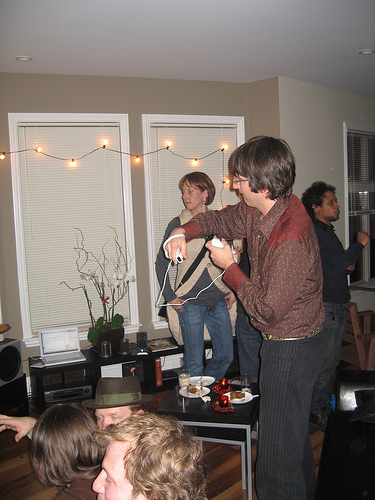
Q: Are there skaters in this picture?
A: No, there are no skaters.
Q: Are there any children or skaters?
A: No, there are no skaters or children.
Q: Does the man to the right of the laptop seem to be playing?
A: Yes, the man is playing.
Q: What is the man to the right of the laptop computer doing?
A: The man is playing.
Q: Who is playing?
A: The man is playing.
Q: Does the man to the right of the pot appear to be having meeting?
A: No, the man is playing.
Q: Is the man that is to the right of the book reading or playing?
A: The man is playing.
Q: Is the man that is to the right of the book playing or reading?
A: The man is playing.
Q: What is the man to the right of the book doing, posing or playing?
A: The man is playing.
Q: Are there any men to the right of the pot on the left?
A: Yes, there is a man to the right of the pot.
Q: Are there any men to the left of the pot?
A: No, the man is to the right of the pot.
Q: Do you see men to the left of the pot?
A: No, the man is to the right of the pot.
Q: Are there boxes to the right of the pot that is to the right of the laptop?
A: No, there is a man to the right of the pot.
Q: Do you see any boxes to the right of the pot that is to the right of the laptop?
A: No, there is a man to the right of the pot.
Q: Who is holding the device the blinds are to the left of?
A: The man is holding the Wii controller.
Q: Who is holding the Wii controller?
A: The man is holding the Wii controller.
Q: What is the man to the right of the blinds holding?
A: The man is holding the Wii remotes.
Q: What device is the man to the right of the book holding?
A: The man is holding the Wii remotes.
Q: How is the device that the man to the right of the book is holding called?
A: The device is a Wii controller.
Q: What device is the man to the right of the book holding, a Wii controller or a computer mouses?
A: The man is holding a Wii controller.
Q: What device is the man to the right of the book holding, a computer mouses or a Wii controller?
A: The man is holding a Wii controller.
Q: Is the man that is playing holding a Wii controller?
A: Yes, the man is holding a Wii controller.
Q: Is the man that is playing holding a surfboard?
A: No, the man is holding a Wii controller.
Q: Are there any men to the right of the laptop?
A: Yes, there is a man to the right of the laptop.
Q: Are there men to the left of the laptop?
A: No, the man is to the right of the laptop.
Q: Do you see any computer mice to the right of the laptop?
A: No, there is a man to the right of the laptop.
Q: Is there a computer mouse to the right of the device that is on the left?
A: No, there is a man to the right of the laptop.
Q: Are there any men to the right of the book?
A: Yes, there is a man to the right of the book.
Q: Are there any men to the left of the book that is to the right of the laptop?
A: No, the man is to the right of the book.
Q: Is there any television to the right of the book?
A: No, there is a man to the right of the book.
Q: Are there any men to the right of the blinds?
A: Yes, there is a man to the right of the blinds.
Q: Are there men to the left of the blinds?
A: No, the man is to the right of the blinds.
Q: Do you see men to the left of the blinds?
A: No, the man is to the right of the blinds.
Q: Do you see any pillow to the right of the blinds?
A: No, there is a man to the right of the blinds.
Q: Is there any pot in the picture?
A: Yes, there is a pot.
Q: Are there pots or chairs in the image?
A: Yes, there is a pot.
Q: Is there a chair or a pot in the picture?
A: Yes, there is a pot.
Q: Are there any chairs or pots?
A: Yes, there is a pot.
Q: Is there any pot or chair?
A: Yes, there is a pot.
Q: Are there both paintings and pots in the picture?
A: No, there is a pot but no paintings.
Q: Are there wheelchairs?
A: No, there are no wheelchairs.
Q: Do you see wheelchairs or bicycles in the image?
A: No, there are no wheelchairs or bicycles.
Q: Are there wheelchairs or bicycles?
A: No, there are no wheelchairs or bicycles.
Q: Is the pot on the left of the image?
A: Yes, the pot is on the left of the image.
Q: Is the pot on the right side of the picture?
A: No, the pot is on the left of the image.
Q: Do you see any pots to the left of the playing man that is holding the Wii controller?
A: Yes, there is a pot to the left of the man.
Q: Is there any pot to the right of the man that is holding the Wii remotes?
A: No, the pot is to the left of the man.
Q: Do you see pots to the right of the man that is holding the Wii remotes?
A: No, the pot is to the left of the man.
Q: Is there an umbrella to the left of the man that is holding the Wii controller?
A: No, there is a pot to the left of the man.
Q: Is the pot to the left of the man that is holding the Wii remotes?
A: Yes, the pot is to the left of the man.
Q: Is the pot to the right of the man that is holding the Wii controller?
A: No, the pot is to the left of the man.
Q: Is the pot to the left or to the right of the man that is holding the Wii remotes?
A: The pot is to the left of the man.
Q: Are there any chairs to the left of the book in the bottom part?
A: No, there is a pot to the left of the book.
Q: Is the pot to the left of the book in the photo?
A: Yes, the pot is to the left of the book.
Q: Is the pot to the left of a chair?
A: No, the pot is to the left of the book.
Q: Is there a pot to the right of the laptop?
A: Yes, there is a pot to the right of the laptop.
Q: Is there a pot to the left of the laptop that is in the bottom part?
A: No, the pot is to the right of the laptop.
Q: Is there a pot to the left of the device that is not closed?
A: No, the pot is to the right of the laptop.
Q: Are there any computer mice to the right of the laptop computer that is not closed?
A: No, there is a pot to the right of the laptop.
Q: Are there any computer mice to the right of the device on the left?
A: No, there is a pot to the right of the laptop.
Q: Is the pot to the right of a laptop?
A: Yes, the pot is to the right of a laptop.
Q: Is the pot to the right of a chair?
A: No, the pot is to the right of a laptop.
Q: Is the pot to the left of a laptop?
A: No, the pot is to the right of a laptop.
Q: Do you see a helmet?
A: No, there are no helmets.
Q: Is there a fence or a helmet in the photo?
A: No, there are no helmets or fences.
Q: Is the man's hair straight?
A: No, the hair is curly.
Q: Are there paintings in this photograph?
A: No, there are no paintings.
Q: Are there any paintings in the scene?
A: No, there are no paintings.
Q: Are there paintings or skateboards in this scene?
A: No, there are no paintings or skateboards.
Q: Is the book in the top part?
A: No, the book is in the bottom of the image.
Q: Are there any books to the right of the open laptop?
A: Yes, there is a book to the right of the laptop computer.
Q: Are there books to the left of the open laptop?
A: No, the book is to the right of the laptop computer.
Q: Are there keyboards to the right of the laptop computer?
A: No, there is a book to the right of the laptop computer.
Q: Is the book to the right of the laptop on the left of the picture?
A: Yes, the book is to the right of the laptop.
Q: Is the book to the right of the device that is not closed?
A: Yes, the book is to the right of the laptop.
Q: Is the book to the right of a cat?
A: No, the book is to the right of the laptop.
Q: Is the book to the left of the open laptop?
A: No, the book is to the right of the laptop computer.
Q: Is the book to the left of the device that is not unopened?
A: No, the book is to the right of the laptop computer.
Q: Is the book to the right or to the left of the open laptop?
A: The book is to the right of the laptop.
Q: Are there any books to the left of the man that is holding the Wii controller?
A: Yes, there is a book to the left of the man.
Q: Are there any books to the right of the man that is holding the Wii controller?
A: No, the book is to the left of the man.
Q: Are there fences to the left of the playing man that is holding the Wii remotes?
A: No, there is a book to the left of the man.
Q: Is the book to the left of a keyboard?
A: No, the book is to the left of the man.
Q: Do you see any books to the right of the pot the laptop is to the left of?
A: Yes, there is a book to the right of the pot.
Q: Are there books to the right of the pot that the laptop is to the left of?
A: Yes, there is a book to the right of the pot.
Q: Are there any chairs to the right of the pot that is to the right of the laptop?
A: No, there is a book to the right of the pot.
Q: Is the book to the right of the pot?
A: Yes, the book is to the right of the pot.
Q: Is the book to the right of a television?
A: No, the book is to the right of the pot.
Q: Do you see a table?
A: Yes, there is a table.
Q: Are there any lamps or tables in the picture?
A: Yes, there is a table.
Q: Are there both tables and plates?
A: Yes, there are both a table and a plate.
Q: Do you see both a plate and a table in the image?
A: Yes, there are both a table and a plate.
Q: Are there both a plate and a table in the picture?
A: Yes, there are both a table and a plate.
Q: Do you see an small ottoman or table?
A: Yes, there is a small table.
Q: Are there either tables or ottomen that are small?
A: Yes, the table is small.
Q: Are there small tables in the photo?
A: Yes, there is a small table.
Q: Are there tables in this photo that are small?
A: Yes, there is a table that is small.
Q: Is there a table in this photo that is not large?
A: Yes, there is a small table.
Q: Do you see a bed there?
A: No, there are no beds.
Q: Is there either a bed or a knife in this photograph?
A: No, there are no beds or knives.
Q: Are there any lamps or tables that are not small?
A: No, there is a table but it is small.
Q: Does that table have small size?
A: Yes, the table is small.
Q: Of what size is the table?
A: The table is small.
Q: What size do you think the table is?
A: The table is small.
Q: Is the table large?
A: No, the table is small.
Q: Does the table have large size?
A: No, the table is small.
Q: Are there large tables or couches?
A: No, there is a table but it is small.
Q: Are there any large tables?
A: No, there is a table but it is small.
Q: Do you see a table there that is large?
A: No, there is a table but it is small.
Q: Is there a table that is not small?
A: No, there is a table but it is small.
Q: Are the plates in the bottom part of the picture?
A: Yes, the plates are in the bottom of the image.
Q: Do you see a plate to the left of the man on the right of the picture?
A: Yes, there are plates to the left of the man.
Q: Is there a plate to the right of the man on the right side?
A: No, the plates are to the left of the man.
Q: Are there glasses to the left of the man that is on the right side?
A: No, there are plates to the left of the man.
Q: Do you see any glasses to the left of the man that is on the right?
A: No, there are plates to the left of the man.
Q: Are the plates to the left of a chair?
A: No, the plates are to the left of the man.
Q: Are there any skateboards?
A: No, there are no skateboards.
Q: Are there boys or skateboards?
A: No, there are no skateboards or boys.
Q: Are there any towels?
A: No, there are no towels.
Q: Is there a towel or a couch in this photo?
A: No, there are no towels or couches.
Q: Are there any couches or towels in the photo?
A: No, there are no towels or couches.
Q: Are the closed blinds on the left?
A: Yes, the blinds are on the left of the image.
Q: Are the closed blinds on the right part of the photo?
A: No, the blinds are on the left of the image.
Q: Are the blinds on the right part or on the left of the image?
A: The blinds are on the left of the image.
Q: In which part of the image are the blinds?
A: The blinds are on the left of the image.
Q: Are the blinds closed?
A: Yes, the blinds are closed.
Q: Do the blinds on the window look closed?
A: Yes, the blinds are closed.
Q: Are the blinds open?
A: No, the blinds are closed.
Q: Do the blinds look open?
A: No, the blinds are closed.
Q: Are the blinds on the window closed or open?
A: The blinds are closed.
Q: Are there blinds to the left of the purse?
A: Yes, there are blinds to the left of the purse.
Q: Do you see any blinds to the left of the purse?
A: Yes, there are blinds to the left of the purse.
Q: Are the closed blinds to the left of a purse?
A: Yes, the blinds are to the left of a purse.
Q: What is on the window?
A: The blinds are on the window.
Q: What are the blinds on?
A: The blinds are on the window.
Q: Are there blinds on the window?
A: Yes, there are blinds on the window.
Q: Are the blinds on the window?
A: Yes, the blinds are on the window.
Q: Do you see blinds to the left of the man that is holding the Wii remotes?
A: Yes, there are blinds to the left of the man.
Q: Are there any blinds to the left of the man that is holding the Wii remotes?
A: Yes, there are blinds to the left of the man.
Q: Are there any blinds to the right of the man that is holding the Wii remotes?
A: No, the blinds are to the left of the man.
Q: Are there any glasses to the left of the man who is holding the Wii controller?
A: No, there are blinds to the left of the man.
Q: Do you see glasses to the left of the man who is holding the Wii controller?
A: No, there are blinds to the left of the man.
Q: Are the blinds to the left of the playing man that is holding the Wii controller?
A: Yes, the blinds are to the left of the man.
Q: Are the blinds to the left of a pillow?
A: No, the blinds are to the left of the man.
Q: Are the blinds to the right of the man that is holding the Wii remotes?
A: No, the blinds are to the left of the man.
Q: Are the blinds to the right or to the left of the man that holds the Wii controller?
A: The blinds are to the left of the man.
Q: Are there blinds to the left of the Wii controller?
A: Yes, there are blinds to the left of the Wii controller.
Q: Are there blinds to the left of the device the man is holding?
A: Yes, there are blinds to the left of the Wii controller.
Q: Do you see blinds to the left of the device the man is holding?
A: Yes, there are blinds to the left of the Wii controller.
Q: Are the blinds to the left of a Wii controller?
A: Yes, the blinds are to the left of a Wii controller.